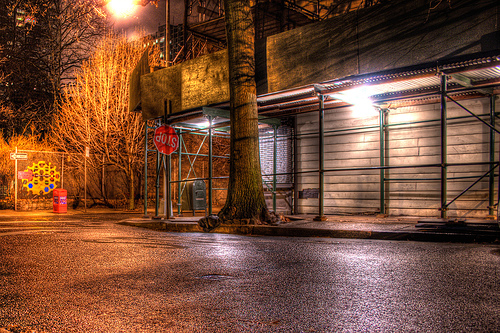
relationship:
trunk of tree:
[194, 136, 294, 234] [195, 3, 295, 235]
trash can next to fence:
[50, 184, 70, 215] [9, 142, 226, 215]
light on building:
[336, 76, 414, 133] [147, 10, 495, 240]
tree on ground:
[52, 26, 161, 209] [7, 196, 495, 330]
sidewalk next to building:
[280, 215, 492, 237] [256, 0, 498, 227]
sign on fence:
[10, 153, 31, 162] [2, 148, 209, 213]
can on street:
[183, 177, 208, 214] [10, 230, 498, 331]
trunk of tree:
[218, 184, 275, 231] [215, 7, 268, 224]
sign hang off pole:
[152, 124, 180, 155] [158, 114, 182, 221]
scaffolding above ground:
[141, 13, 498, 66] [113, 201, 404, 311]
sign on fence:
[7, 148, 30, 162] [9, 142, 226, 215]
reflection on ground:
[244, 227, 459, 332] [0, 212, 498, 329]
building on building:
[127, 11, 500, 226] [112, 1, 497, 249]